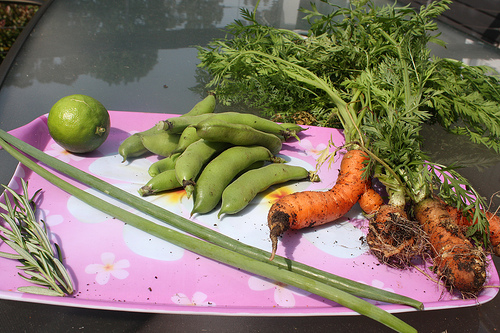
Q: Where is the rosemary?
A: On the left.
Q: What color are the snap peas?
A: Green.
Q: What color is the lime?
A: Green.